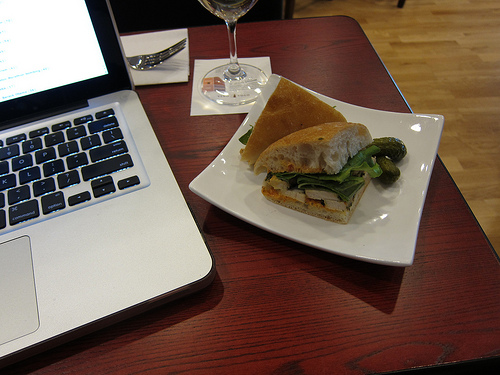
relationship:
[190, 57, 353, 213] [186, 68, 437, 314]
napkin under plate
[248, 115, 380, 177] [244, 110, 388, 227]
bun on sandwich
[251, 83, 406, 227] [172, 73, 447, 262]
lunch on plate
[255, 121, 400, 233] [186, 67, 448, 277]
sandwich on plate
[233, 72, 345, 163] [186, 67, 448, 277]
sandwich on plate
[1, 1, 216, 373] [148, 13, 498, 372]
laptop on table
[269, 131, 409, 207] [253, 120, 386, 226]
lettuce on sandwich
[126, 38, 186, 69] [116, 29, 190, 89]
fork on napkin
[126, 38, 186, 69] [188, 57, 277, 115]
fork on napkin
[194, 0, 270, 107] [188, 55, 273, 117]
glass on napkin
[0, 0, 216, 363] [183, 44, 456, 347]
laptop on desk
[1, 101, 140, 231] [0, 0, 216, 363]
keys on laptop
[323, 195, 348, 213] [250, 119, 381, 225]
chicken on sandwich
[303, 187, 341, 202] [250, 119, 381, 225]
chicken on sandwich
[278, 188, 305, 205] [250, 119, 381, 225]
chicken on sandwich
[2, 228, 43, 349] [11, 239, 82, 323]
mouse pad on computer